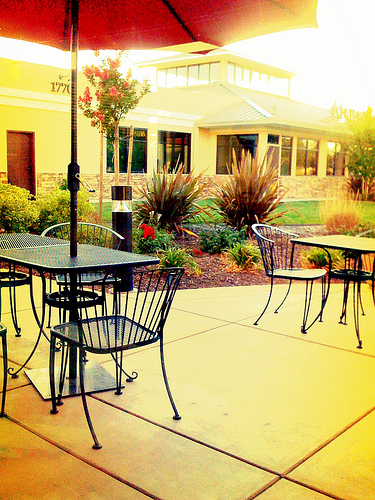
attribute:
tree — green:
[76, 48, 151, 185]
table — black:
[282, 205, 374, 305]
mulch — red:
[106, 218, 331, 286]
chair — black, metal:
[46, 257, 192, 454]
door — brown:
[2, 129, 45, 190]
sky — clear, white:
[317, 25, 363, 98]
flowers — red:
[131, 216, 162, 244]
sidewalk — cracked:
[208, 285, 258, 375]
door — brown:
[6, 130, 38, 199]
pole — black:
[112, 183, 135, 291]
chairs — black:
[41, 264, 189, 449]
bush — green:
[1, 180, 109, 245]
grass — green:
[92, 183, 337, 235]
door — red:
[5, 115, 60, 214]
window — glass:
[266, 133, 292, 174]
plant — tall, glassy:
[132, 152, 218, 239]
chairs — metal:
[49, 264, 184, 445]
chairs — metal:
[253, 219, 327, 339]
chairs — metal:
[329, 227, 374, 345]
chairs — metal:
[40, 219, 123, 389]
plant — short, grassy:
[145, 244, 205, 285]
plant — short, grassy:
[132, 221, 175, 253]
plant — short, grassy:
[198, 218, 245, 257]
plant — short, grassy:
[302, 243, 348, 273]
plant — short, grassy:
[310, 189, 365, 240]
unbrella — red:
[1, 1, 333, 62]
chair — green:
[225, 205, 327, 287]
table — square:
[288, 218, 372, 263]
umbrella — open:
[1, 1, 330, 56]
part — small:
[84, 245, 130, 274]